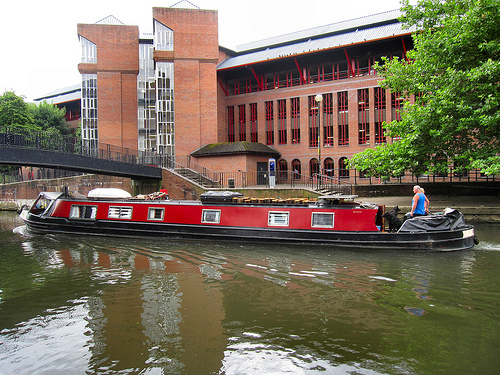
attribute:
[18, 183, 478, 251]
houseboat — long, red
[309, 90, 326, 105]
light — white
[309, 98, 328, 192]
post — black, metal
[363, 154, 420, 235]
dogs — black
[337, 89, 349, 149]
window — tall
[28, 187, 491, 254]
boat — long, RED 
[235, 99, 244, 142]
window — tall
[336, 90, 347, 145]
window — tall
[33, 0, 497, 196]
garage — parking garage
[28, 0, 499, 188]
building — large, brick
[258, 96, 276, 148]
window — tall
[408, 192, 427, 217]
blue top — bright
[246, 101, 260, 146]
window — tall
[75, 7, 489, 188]
garage — parking garage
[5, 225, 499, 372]
lake — small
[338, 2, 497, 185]
tree — large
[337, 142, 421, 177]
leaves — green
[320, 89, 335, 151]
window — tall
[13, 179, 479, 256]
boat — red , small 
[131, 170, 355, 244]
boat — red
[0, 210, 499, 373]
water — green 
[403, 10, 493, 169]
trees — growing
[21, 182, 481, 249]
boat — red